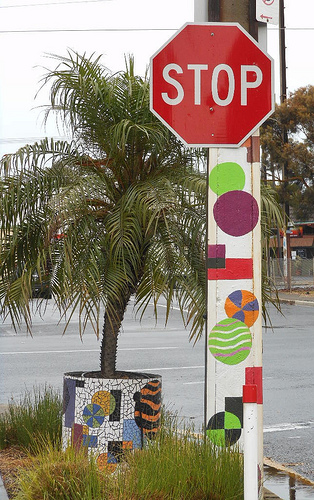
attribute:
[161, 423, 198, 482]
grass — tall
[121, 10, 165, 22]
sky — cloudy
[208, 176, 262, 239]
circle — orange, purple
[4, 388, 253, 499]
grass — green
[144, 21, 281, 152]
sign — red, white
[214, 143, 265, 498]
pole — white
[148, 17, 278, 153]
top — red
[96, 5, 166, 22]
sky — bright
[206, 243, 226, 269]
square — purple, black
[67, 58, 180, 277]
leaves — green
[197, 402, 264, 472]
circle — green, black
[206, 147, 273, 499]
post — circle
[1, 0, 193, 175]
cloud — white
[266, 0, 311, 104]
cloud — white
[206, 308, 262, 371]
circle — green,  stripes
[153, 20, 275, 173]
sign — stop